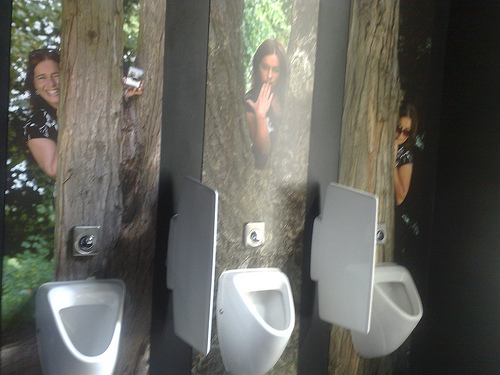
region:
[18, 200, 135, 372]
A urinal on a tree.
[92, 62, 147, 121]
A hand holding a picture.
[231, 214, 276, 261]
A silver push button.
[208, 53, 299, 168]
A person acting suprised.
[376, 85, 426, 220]
A woman wearing sun glasses.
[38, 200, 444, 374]
Three urinals in a row.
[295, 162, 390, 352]
The top of a toilet.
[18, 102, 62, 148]
A black and white shirt sleeve.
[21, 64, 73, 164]
A woman smiling for picture.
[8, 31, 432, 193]
Three woman in a row.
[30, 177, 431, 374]
Toilets of man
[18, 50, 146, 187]
Woman behind a trunk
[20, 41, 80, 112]
Woman is happy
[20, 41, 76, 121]
Woman smile and show teeth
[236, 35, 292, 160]
Woman has hand on mouth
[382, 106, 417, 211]
Woman wears sunglasses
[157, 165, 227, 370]
Divider between toilets is white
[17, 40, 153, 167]
Woman holds something on left hand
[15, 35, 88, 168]
Woman wears black dress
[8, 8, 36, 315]
Plants behind people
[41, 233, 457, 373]
three urinals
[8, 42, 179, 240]
a picture of a lady looking at you at a urinal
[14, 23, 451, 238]
three people pictured peeking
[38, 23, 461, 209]
pictures of three ladies looking at urinals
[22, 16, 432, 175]
the women pictured are between trees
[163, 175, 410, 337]
two dividers of the urinals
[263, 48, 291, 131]
lady has her hand on her face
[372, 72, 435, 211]
lady is wearing sunglasses in this photo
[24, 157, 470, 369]
a bathroom with three urinals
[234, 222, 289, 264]
a flusher for the urinal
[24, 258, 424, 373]
three urinals on a wall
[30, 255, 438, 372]
the urinals are white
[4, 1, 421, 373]
the wall has pictures on it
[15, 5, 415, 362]
the pictures have trees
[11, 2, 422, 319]
the trees have women looking around them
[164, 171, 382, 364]
the urinals have dividers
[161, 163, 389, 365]
the dividers are white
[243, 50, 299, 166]
the woman in the middle looks like she is laughing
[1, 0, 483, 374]
the pictures are on a black wall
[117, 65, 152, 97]
the woman on the end is holding a camera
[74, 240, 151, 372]
3 urinals are in the photo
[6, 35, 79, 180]
the girl is peeking out from behind the tree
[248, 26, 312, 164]
the girl appears embarrassed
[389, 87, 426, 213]
the girl is wearing sunglasses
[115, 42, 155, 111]
the girl is holding something in her hand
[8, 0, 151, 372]
the urinal appears to be attached to the tree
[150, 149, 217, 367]
there are seperaters between the urinals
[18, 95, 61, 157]
the girls shirt is black & white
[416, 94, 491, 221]
the background is dark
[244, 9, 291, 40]
there are trees in the background